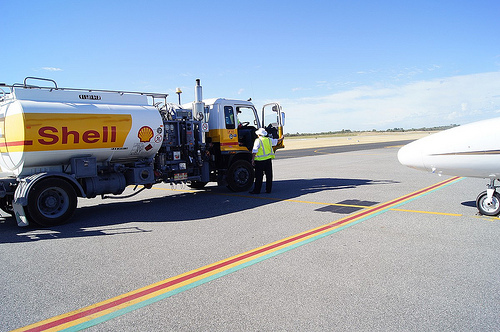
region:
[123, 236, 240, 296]
the line is red, yellow, and blue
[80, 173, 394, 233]
shadow on the ground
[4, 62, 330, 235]
the truck has fuel tank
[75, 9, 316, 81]
the sky is blue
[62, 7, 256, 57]
the sky is clear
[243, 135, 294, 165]
man is wearing a vest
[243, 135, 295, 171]
the vest is neon gray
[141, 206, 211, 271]
the ground is gray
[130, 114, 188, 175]
the logo is yellow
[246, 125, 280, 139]
the hat is white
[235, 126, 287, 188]
A man standing by the door.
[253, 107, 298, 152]
The door of the trunk is open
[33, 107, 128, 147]
the tank has the word "shell" written on it.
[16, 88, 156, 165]
The tanker is white and yellow.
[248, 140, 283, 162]
The man is wearing a green vest.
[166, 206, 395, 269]
The street has lines in the middle.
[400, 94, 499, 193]
A plane is parked on the side.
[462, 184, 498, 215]
The wheels of a small plane.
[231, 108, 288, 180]
The man is talking to the person in the truck.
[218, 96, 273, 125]
The top of the truck is white.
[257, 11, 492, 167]
The sky is blue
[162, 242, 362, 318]
The ground is gray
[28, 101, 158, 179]
The truck says shell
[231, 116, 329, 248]
The man is stading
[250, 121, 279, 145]
The man has a helmet on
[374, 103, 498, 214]
This is a plane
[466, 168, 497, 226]
The plane has a wheel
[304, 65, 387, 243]
There are trees in the distance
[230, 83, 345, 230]
The door is open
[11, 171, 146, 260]
The wheels are parked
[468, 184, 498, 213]
front airplane tire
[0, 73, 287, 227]
long yellow and white gas truck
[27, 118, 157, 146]
name of truck carrier and logo on side of truck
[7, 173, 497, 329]
red, yellow and green traffic line on grey tarmac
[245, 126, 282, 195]
airport worker in neon green vest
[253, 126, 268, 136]
white hat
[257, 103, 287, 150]
truck passengers side door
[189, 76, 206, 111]
metal smoke emitter at top of truck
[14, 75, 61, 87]
metal hand rail on top of truck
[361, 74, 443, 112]
white cloud in blue sky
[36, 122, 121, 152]
The shell company logo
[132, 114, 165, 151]
The seashell company logo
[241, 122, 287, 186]
A man in a safety vest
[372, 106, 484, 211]
The nose of a small plane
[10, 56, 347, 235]
a shell fueling truck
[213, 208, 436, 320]
A concrete run way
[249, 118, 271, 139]
A white mens hat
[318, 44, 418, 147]
A blue sjy with clouds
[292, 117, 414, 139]
A tree line in the distance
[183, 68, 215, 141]
A trucks exhaust system